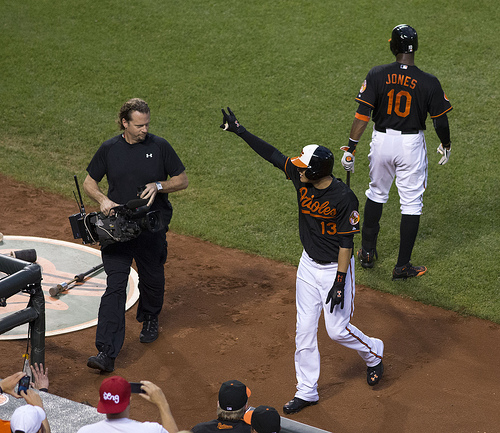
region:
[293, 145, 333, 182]
A black, orange, and white helmet.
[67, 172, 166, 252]
A large black filming camera.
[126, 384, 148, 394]
A black cell phone turned sideways.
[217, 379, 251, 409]
A black and orange ball cap.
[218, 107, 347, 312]
Black batting gloves.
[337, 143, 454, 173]
Orange and white batting gloves.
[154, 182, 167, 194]
A wristwatch.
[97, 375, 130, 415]
A red and white ball cap turned backwards.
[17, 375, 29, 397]
A blue and black cellphone.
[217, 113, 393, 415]
A black, orange, and white baseball uniform.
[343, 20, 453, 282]
a baseball player holding a baseball bat on its head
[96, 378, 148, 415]
man taking a picture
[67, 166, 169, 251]
cameraman holding a black camera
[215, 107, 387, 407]
a baseball player saluting fans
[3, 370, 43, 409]
a man holding a cellphone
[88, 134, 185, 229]
man wearing a black shirt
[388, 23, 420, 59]
man wearing a black hard hat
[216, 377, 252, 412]
man wearing a black and orange cap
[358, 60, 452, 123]
man wearing a black and orange shirt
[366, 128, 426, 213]
man wearing white knee pants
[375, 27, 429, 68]
player has black cap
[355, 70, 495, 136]
black and orange shirt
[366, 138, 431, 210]
player has white pants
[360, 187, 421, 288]
player has long black socks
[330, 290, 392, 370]
black and orange stripes on pants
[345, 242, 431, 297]
black and orange shoes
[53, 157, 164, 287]
man is carrying camera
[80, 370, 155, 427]
man has red hat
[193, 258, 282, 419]
brown dirt near player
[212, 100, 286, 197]
man is wearing black glove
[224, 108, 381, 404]
A baseball player walking off the field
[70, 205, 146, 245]
A camera pointed at the baseball player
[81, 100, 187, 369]
A man with a large camera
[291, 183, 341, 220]
The Orioles logo on the jersey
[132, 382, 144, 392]
A cell phone pointed at the field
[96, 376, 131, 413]
This person is wearing a hat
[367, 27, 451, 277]
A baseball player on the field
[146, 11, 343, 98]
The green part of the baseball field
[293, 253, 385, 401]
The player's pants are white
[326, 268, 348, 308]
A glove on his left hand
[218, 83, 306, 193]
man's arm is in air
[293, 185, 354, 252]
orange letters on man's shirt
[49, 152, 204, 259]
man holding a camera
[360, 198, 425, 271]
man's socks are black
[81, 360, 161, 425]
man holding a camera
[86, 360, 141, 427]
man's hat is red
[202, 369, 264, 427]
man's hat is orange and black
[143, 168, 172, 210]
man wearing a watch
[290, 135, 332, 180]
man's helmet is black orange and white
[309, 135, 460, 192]
man wearing white gloves